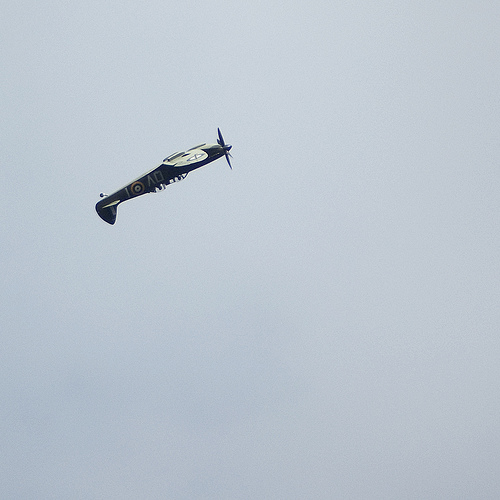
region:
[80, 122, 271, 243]
This is a jet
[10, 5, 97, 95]
Section of the sky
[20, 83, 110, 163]
Section of the sky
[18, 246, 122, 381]
Section of the sky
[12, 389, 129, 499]
Section of the sky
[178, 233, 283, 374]
Section of the sky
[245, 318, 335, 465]
Section of the sky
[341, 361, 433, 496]
Section of the sky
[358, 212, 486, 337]
Section of the sky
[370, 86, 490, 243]
Section of the sky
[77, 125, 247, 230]
blue plane flying in air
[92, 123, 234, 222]
blue and white plane flying in air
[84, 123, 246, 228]
blue and white plane flying upside down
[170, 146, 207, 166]
\white bottom of wing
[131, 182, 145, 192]
target on side of plane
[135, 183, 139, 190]
white circle on target of plane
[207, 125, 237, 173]
front propeller of plane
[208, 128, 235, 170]
black propeller of plane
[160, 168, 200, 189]
small cockpit of plane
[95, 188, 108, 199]
small black wheel on back of plane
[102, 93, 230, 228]
AIRPLANE UPSIDE DOWN IN AIR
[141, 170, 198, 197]
GLASS COCKPIT OF PLANE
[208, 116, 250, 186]
PROPELLER ON FRONT OF PLANE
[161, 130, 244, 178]
WHITE UNDERBELLY OF PLANE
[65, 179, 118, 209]
SMALL WHEEL ON REAR OF PLANE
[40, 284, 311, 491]
GRAY OVERCAST CLOUDS IN SKY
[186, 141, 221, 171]
SMALL LOGO UNDER WING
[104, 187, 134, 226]
TAIL ON REAR OF PLANE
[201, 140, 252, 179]
NOSE OF AIRPLANE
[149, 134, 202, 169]
RAISED LANDING GEAR OF PLANE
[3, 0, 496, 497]
a clear pale gray blue sky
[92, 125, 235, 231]
a plane flying upside down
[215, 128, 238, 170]
the propeler of an airplane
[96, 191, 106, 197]
the tail wheel of an airplane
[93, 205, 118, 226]
the tail of an airplane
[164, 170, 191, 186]
the cockpit of an airplane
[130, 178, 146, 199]
a target drawn on an airplane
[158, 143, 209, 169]
the wing of an airplane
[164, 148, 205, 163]
the white underside of a wing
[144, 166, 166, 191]
letters on the side of an airplane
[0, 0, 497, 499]
blue sky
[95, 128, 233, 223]
an airplane upside down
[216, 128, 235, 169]
the engine of an airplane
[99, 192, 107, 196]
rear wheel of an airplane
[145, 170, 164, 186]
white letters on an airplane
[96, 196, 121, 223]
tail of an airplane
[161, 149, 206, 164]
left wing of an airplane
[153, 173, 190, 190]
cabin of an airplane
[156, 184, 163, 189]
person inside of an airplane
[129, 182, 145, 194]
yellow and white circles